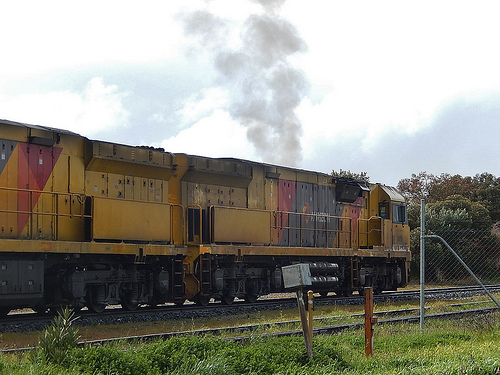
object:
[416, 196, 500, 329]
fence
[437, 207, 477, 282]
trees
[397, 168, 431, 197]
trees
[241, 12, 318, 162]
steam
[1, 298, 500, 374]
grass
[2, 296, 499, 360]
tracks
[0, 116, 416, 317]
train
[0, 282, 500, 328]
tracks